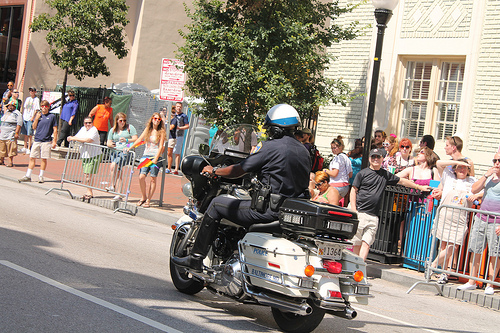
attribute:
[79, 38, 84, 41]
leaves — green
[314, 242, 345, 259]
plate — license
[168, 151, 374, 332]
motorcycle — white and black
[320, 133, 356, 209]
girl — young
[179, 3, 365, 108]
leaves — green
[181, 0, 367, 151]
tree — planted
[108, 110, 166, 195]
women — standing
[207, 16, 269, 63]
leaves — green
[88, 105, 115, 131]
tee shirt — orange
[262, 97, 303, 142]
helmet — blue , white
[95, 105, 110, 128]
shirt — orange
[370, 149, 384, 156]
cap — black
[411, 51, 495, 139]
windows — white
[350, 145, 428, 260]
man — leaning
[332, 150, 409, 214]
shirt — black, tee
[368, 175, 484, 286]
rail — guard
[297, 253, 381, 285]
lights — red, yellow